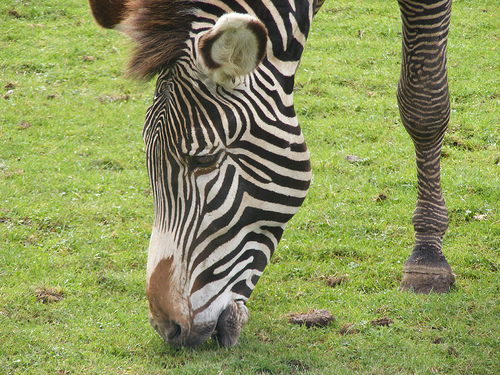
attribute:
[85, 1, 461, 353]
zebra — white, black, eating, striped, eatig, grazig, here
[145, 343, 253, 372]
grass — green, brow, gree, short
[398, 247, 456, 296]
hoof — black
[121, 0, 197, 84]
mane — short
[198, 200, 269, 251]
stripes — black